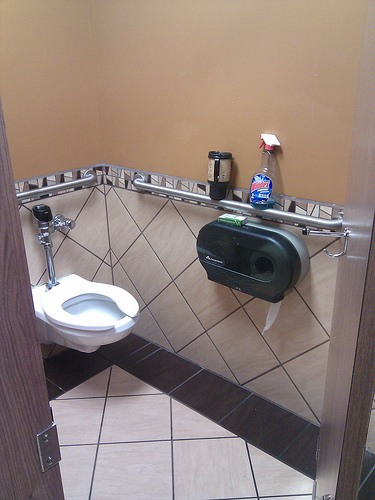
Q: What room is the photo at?
A: It is at the bathroom.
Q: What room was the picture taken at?
A: It was taken at the bathroom.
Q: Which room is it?
A: It is a bathroom.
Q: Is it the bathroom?
A: Yes, it is the bathroom.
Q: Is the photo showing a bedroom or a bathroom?
A: It is showing a bathroom.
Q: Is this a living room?
A: No, it is a bathroom.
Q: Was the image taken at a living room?
A: No, the picture was taken in a bathroom.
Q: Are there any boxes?
A: No, there are no boxes.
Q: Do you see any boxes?
A: No, there are no boxes.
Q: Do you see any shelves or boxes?
A: No, there are no boxes or shelves.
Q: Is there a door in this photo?
A: Yes, there is a door.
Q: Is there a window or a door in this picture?
A: Yes, there is a door.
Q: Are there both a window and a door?
A: No, there is a door but no windows.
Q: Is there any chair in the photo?
A: No, there are no chairs.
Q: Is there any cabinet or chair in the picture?
A: No, there are no chairs or cabinets.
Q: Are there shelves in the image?
A: No, there are no shelves.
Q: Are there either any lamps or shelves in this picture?
A: No, there are no shelves or lamps.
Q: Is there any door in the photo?
A: Yes, there is a door.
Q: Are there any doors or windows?
A: Yes, there is a door.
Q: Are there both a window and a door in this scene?
A: No, there is a door but no windows.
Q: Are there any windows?
A: No, there are no windows.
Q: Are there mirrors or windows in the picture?
A: No, there are no windows or mirrors.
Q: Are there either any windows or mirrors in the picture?
A: No, there are no windows or mirrors.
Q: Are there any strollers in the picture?
A: No, there are no strollers.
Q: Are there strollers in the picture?
A: No, there are no strollers.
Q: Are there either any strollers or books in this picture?
A: No, there are no strollers or books.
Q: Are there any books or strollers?
A: No, there are no strollers or books.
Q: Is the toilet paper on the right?
A: Yes, the toilet paper is on the right of the image.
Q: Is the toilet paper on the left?
A: No, the toilet paper is on the right of the image.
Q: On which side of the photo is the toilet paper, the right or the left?
A: The toilet paper is on the right of the image.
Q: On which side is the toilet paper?
A: The toilet paper is on the right of the image.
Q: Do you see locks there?
A: No, there are no locks.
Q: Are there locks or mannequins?
A: No, there are no locks or mannequins.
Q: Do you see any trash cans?
A: No, there are no trash cans.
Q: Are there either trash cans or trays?
A: No, there are no trash cans or trays.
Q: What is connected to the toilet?
A: The pipe is connected to the toilet.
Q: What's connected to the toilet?
A: The pipe is connected to the toilet.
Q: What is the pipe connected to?
A: The pipe is connected to the toilet.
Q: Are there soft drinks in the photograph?
A: No, there are no soft drinks.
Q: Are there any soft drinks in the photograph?
A: No, there are no soft drinks.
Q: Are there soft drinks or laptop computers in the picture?
A: No, there are no soft drinks or laptop computers.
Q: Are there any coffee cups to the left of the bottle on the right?
A: Yes, there is a coffee cup to the left of the bottle.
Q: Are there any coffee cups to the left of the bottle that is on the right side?
A: Yes, there is a coffee cup to the left of the bottle.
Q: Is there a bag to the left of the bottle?
A: No, there is a coffee cup to the left of the bottle.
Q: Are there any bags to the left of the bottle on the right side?
A: No, there is a coffee cup to the left of the bottle.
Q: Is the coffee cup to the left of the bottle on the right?
A: Yes, the coffee cup is to the left of the bottle.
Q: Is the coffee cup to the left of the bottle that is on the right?
A: Yes, the coffee cup is to the left of the bottle.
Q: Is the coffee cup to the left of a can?
A: No, the coffee cup is to the left of the bottle.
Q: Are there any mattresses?
A: No, there are no mattresses.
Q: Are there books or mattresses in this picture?
A: No, there are no mattresses or books.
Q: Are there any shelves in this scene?
A: No, there are no shelves.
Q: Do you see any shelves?
A: No, there are no shelves.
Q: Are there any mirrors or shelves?
A: No, there are no shelves or mirrors.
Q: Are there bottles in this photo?
A: Yes, there is a bottle.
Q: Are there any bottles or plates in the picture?
A: Yes, there is a bottle.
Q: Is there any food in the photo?
A: No, there is no food.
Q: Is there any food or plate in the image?
A: No, there are no food or plates.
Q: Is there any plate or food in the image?
A: No, there are no food or plates.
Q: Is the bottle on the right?
A: Yes, the bottle is on the right of the image.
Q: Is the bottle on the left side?
A: No, the bottle is on the right of the image.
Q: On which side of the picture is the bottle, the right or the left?
A: The bottle is on the right of the image.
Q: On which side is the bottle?
A: The bottle is on the right of the image.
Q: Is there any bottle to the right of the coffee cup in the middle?
A: Yes, there is a bottle to the right of the coffee cup.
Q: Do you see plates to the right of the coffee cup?
A: No, there is a bottle to the right of the coffee cup.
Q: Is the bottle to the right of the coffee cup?
A: Yes, the bottle is to the right of the coffee cup.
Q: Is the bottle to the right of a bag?
A: No, the bottle is to the right of the coffee cup.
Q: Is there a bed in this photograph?
A: No, there are no beds.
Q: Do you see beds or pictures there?
A: No, there are no beds or pictures.